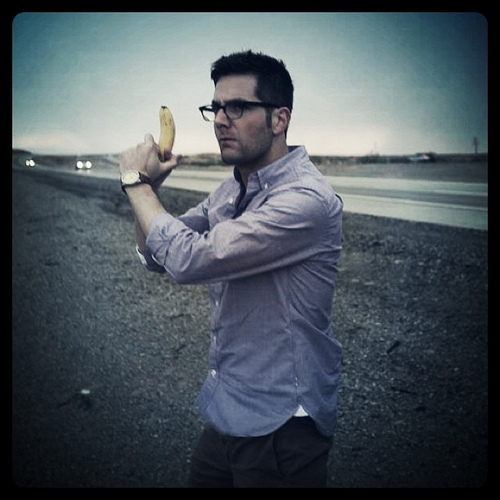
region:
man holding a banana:
[121, 51, 334, 496]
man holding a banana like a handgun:
[115, 51, 341, 495]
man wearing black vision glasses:
[194, 51, 301, 164]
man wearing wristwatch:
[117, 161, 148, 189]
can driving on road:
[74, 156, 94, 173]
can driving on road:
[23, 158, 34, 166]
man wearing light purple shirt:
[151, 155, 342, 432]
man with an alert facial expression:
[198, 51, 292, 171]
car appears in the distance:
[407, 147, 431, 164]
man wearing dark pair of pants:
[186, 415, 338, 498]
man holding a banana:
[122, 94, 340, 464]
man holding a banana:
[107, 51, 383, 381]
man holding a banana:
[133, 43, 372, 387]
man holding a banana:
[110, 58, 350, 298]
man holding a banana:
[105, 65, 376, 310]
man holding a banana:
[106, 39, 383, 327]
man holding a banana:
[82, 45, 385, 374]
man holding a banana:
[100, 59, 377, 330]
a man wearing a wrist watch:
[115, 165, 152, 193]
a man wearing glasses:
[195, 98, 297, 128]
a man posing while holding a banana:
[118, 38, 346, 498]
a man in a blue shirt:
[135, 142, 345, 441]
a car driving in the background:
[70, 155, 95, 172]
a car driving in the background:
[24, 155, 38, 169]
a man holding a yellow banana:
[140, 99, 182, 185]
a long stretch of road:
[12, 137, 492, 239]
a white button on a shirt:
[206, 365, 218, 378]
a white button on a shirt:
[211, 334, 218, 345]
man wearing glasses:
[192, 55, 347, 175]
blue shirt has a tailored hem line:
[143, 144, 343, 441]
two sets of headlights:
[16, 140, 93, 180]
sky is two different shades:
[300, 16, 475, 131]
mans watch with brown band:
[111, 166, 156, 186]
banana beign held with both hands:
[140, 96, 181, 171]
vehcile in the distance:
[400, 146, 445, 162]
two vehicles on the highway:
[16, 145, 101, 170]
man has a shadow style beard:
[201, 50, 316, 165]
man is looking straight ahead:
[197, 46, 299, 164]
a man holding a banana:
[116, 45, 379, 395]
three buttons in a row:
[194, 293, 236, 394]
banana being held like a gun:
[108, 95, 188, 211]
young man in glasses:
[197, 49, 294, 166]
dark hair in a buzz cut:
[201, 48, 314, 95]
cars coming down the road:
[17, 124, 111, 176]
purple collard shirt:
[215, 143, 329, 188]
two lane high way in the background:
[351, 163, 493, 235]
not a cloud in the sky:
[303, 63, 498, 158]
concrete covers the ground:
[354, 278, 485, 373]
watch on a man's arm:
[114, 165, 153, 192]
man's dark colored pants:
[182, 403, 336, 495]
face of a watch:
[121, 166, 143, 190]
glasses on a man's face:
[192, 99, 272, 121]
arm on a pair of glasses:
[241, 98, 276, 113]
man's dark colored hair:
[208, 43, 293, 134]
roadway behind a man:
[27, 154, 496, 235]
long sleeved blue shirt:
[136, 140, 353, 445]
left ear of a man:
[270, 104, 291, 143]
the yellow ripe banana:
[156, 105, 175, 157]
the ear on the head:
[273, 106, 289, 134]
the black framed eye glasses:
[196, 100, 291, 120]